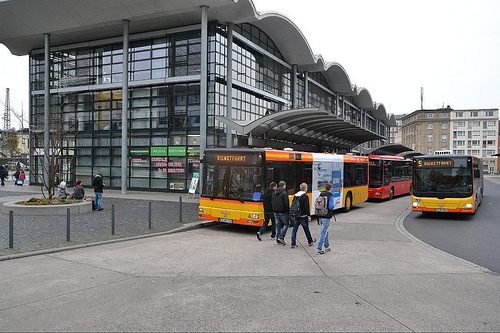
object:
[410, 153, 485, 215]
bus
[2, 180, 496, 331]
street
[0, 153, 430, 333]
bus stop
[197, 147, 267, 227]
front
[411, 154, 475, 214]
front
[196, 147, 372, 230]
bus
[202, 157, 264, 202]
windshield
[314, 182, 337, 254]
person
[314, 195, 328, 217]
backpack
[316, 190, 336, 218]
hoodie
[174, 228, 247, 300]
road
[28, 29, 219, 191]
building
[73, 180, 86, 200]
people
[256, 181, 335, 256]
people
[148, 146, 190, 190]
advertisement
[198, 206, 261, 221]
headlights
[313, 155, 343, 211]
paper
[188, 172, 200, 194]
sign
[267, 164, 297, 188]
window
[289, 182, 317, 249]
man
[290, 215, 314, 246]
jeans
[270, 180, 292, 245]
person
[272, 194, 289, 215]
coat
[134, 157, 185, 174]
sign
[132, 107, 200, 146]
windo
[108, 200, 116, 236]
post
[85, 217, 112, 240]
ground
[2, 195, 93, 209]
circle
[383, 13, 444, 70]
sky